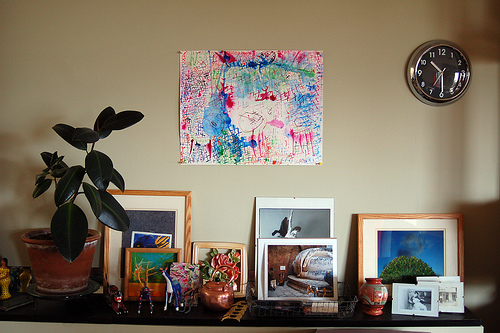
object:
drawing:
[178, 47, 325, 166]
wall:
[2, 1, 499, 332]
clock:
[404, 36, 473, 109]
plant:
[30, 106, 144, 266]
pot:
[20, 226, 101, 294]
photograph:
[377, 230, 447, 285]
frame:
[357, 213, 464, 296]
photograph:
[264, 242, 337, 301]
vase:
[358, 277, 388, 316]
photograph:
[392, 284, 439, 317]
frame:
[102, 189, 193, 301]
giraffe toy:
[159, 267, 183, 313]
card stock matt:
[361, 217, 457, 284]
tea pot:
[197, 266, 238, 313]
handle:
[211, 266, 235, 284]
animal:
[137, 282, 155, 316]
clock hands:
[430, 60, 442, 73]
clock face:
[416, 46, 470, 101]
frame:
[192, 240, 247, 299]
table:
[0, 290, 487, 333]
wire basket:
[246, 282, 358, 320]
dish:
[25, 279, 99, 299]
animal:
[105, 285, 129, 316]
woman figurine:
[0, 257, 10, 299]